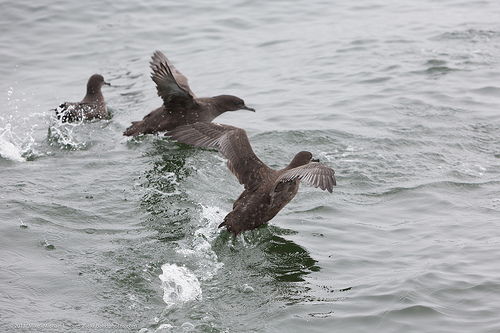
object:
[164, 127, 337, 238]
bird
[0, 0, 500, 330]
water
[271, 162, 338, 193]
wing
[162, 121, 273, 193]
wing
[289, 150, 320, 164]
head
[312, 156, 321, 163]
beak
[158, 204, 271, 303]
splash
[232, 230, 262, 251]
feet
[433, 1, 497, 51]
part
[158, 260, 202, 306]
part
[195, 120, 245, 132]
edge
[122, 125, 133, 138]
part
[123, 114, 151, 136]
tail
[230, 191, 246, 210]
edge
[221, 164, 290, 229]
back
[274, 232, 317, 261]
edge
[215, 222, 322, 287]
shadow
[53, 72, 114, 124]
bird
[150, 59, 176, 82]
feathers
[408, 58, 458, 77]
ripples